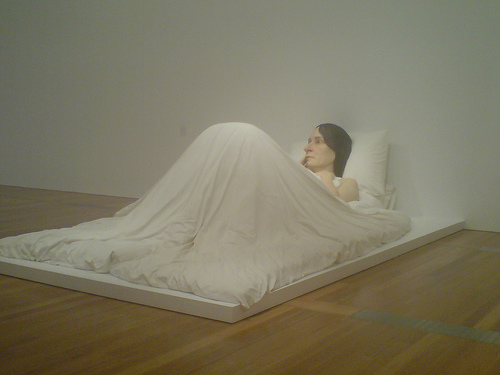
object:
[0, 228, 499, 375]
floor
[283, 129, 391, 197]
pillow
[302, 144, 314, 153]
nose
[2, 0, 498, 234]
wall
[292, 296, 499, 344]
line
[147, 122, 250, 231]
wrinkle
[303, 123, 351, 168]
head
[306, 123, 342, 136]
top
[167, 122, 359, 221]
sculpture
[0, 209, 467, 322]
bed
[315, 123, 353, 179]
hair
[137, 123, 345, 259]
lump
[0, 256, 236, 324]
edge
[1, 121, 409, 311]
bed sheet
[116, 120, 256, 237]
wrinkle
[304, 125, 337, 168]
face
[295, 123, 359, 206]
woman